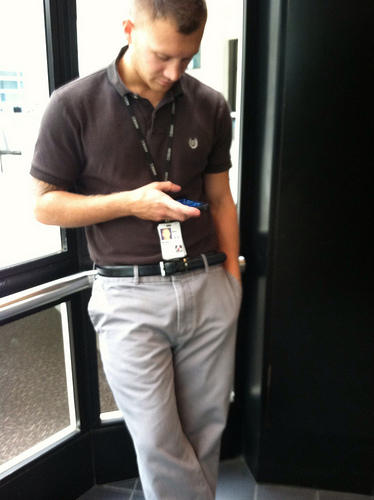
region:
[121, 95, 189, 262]
Lanyard with ID tags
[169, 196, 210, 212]
Cell phone in man's hand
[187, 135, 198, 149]
White logo on black polo shirt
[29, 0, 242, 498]
Man standing in front of window looking at cell phone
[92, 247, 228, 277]
Narrow black belt with silver buckle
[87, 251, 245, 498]
Pair of khaki pants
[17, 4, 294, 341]
man wearing brown shirt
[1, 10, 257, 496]
man wearing khaki pants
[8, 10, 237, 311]
man wearing black belt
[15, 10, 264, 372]
man wearing a badge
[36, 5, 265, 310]
man holding a phone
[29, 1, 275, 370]
man holding hand in his pocket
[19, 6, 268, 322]
man crossing his leg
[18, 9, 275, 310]
man standing near a window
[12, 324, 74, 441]
window near a man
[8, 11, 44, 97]
window near a building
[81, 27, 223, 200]
a man standing inside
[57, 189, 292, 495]
a man wearing khakies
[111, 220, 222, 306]
a man wearing a belt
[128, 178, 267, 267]
a man holding a phone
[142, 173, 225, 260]
a man looking at a phone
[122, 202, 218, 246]
a man holding a cell phone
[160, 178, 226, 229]
a man looking at a cell phone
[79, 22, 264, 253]
a man with short hair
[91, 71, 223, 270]
a man wearing a shirt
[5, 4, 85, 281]
a window behind the man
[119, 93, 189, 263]
a badge hanging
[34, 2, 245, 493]
a man standing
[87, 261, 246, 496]
a pair of grey slacks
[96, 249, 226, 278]
a black leather belt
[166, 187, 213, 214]
a blue and black cellphone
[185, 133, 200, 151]
the logo on the shirt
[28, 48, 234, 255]
a grey polo shirt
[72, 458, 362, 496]
the tiled floor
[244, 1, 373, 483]
the black walls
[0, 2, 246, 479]
the glass window panes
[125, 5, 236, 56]
boy has brown hair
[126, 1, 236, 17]
boy has short hair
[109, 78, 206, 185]
boy is wearing lanyard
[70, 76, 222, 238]
boy has dark grey shirt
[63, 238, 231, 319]
boy has black belt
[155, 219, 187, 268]
ID is on lanyard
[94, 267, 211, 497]
boy has grey pants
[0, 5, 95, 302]
black frame on window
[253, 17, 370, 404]
black door behind boy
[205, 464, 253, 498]
dark grey tile floor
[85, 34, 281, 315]
a man standing inside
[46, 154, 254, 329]
a man on a phone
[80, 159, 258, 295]
a man on a cell phone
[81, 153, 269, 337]
a man holding a phone